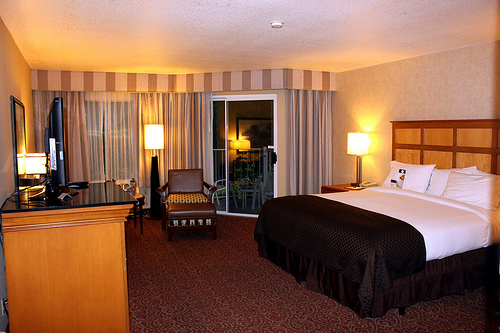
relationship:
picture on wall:
[3, 89, 32, 149] [0, 15, 37, 214]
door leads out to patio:
[198, 92, 280, 221] [212, 96, 272, 213]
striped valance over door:
[26, 58, 346, 95] [198, 92, 280, 221]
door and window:
[198, 92, 280, 221] [61, 79, 151, 196]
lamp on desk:
[346, 132, 372, 182] [314, 177, 378, 199]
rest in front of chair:
[145, 201, 228, 241] [137, 129, 241, 266]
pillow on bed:
[388, 155, 435, 192] [258, 158, 493, 310]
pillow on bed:
[441, 166, 499, 204] [245, 93, 497, 320]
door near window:
[198, 92, 280, 221] [45, 97, 175, 215]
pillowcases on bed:
[427, 168, 449, 199] [252, 107, 499, 325]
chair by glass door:
[160, 168, 220, 241] [210, 97, 282, 221]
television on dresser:
[7, 95, 29, 189] [10, 184, 132, 331]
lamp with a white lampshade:
[346, 132, 372, 182] [346, 130, 373, 159]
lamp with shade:
[333, 132, 398, 206] [332, 130, 377, 157]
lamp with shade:
[143, 122, 169, 220] [139, 117, 174, 155]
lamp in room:
[143, 122, 169, 220] [1, 0, 498, 332]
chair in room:
[158, 165, 220, 242] [1, 0, 498, 332]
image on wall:
[7, 95, 29, 187] [3, 18, 38, 211]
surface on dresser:
[6, 176, 140, 206] [0, 184, 132, 331]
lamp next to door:
[143, 122, 169, 220] [198, 92, 280, 221]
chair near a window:
[160, 168, 220, 241] [220, 106, 277, 211]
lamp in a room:
[24, 152, 46, 179] [1, 0, 498, 332]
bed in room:
[254, 117, 497, 316] [1, 0, 498, 332]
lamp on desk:
[143, 122, 169, 220] [314, 177, 378, 199]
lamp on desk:
[21, 147, 46, 179] [314, 177, 378, 199]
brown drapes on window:
[34, 85, 332, 212] [75, 85, 138, 191]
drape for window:
[39, 92, 91, 186] [73, 92, 147, 202]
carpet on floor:
[115, 191, 351, 328] [92, 157, 496, 314]